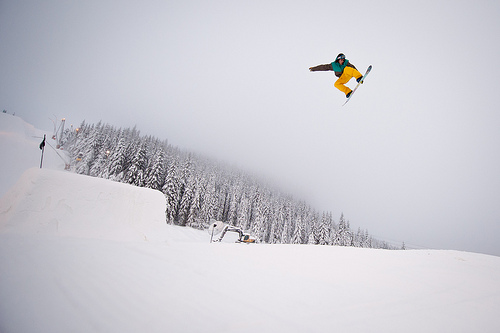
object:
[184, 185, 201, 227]
trees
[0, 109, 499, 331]
snow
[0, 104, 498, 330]
expanse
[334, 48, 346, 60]
hat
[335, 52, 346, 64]
head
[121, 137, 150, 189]
trees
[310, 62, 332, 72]
arm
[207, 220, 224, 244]
object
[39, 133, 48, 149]
black flag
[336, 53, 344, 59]
goggles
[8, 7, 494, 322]
air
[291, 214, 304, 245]
pine trees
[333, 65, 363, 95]
pants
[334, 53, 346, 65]
helmet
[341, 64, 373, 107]
snowboard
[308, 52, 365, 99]
man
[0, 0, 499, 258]
sky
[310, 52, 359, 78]
jacket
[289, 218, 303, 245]
trees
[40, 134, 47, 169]
post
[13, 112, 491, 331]
ground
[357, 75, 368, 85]
hand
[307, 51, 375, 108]
jump